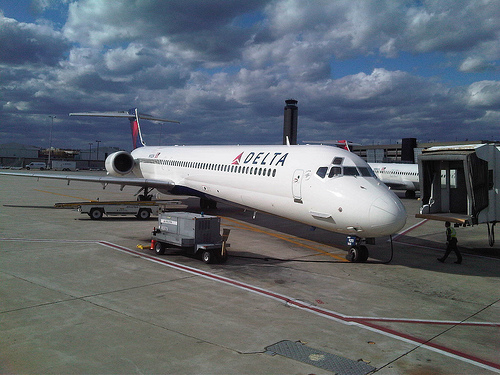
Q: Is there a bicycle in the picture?
A: No, there are no bicycles.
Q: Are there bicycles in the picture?
A: No, there are no bicycles.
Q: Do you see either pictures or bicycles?
A: No, there are no bicycles or pictures.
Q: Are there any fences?
A: No, there are no fences.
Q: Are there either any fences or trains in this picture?
A: No, there are no fences or trains.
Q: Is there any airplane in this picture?
A: Yes, there is an airplane.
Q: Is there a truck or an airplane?
A: Yes, there is an airplane.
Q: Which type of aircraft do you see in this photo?
A: The aircraft is an airplane.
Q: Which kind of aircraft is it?
A: The aircraft is an airplane.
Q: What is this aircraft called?
A: That is an airplane.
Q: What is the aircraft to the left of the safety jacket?
A: The aircraft is an airplane.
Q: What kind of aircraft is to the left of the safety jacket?
A: The aircraft is an airplane.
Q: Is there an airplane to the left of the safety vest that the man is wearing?
A: Yes, there is an airplane to the left of the safety jacket.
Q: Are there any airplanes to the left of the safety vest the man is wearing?
A: Yes, there is an airplane to the left of the safety jacket.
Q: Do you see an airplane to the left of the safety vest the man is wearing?
A: Yes, there is an airplane to the left of the safety jacket.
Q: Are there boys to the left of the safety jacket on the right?
A: No, there is an airplane to the left of the safety jacket.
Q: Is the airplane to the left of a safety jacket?
A: Yes, the airplane is to the left of a safety jacket.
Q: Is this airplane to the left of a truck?
A: No, the airplane is to the left of a safety jacket.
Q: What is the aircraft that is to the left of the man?
A: The aircraft is an airplane.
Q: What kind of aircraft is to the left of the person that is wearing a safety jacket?
A: The aircraft is an airplane.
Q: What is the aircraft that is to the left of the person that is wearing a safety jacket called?
A: The aircraft is an airplane.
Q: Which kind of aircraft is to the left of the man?
A: The aircraft is an airplane.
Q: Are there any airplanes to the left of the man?
A: Yes, there is an airplane to the left of the man.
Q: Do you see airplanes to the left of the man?
A: Yes, there is an airplane to the left of the man.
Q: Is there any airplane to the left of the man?
A: Yes, there is an airplane to the left of the man.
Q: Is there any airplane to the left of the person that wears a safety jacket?
A: Yes, there is an airplane to the left of the man.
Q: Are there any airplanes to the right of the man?
A: No, the airplane is to the left of the man.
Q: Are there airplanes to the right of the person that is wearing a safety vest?
A: No, the airplane is to the left of the man.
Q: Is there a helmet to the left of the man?
A: No, there is an airplane to the left of the man.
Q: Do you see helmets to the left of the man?
A: No, there is an airplane to the left of the man.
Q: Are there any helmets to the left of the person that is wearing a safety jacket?
A: No, there is an airplane to the left of the man.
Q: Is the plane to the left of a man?
A: Yes, the plane is to the left of a man.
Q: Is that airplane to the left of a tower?
A: No, the airplane is to the left of a man.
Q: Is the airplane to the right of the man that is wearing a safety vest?
A: No, the airplane is to the left of the man.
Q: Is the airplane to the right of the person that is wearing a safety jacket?
A: No, the airplane is to the left of the man.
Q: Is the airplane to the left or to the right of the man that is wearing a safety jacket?
A: The airplane is to the left of the man.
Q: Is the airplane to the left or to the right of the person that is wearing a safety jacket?
A: The airplane is to the left of the man.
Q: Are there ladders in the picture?
A: No, there are no ladders.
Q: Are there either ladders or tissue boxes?
A: No, there are no ladders or tissue boxes.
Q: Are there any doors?
A: Yes, there is a door.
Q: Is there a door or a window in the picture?
A: Yes, there is a door.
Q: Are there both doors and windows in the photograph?
A: Yes, there are both a door and a window.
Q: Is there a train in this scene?
A: No, there are no trains.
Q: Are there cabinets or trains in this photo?
A: No, there are no trains or cabinets.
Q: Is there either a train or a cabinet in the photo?
A: No, there are no trains or cabinets.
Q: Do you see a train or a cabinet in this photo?
A: No, there are no trains or cabinets.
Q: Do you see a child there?
A: No, there are no children.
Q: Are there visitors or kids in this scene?
A: No, there are no kids or visitors.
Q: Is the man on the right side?
A: Yes, the man is on the right of the image.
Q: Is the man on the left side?
A: No, the man is on the right of the image.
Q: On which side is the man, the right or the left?
A: The man is on the right of the image.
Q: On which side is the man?
A: The man is on the right of the image.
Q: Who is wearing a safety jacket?
A: The man is wearing a safety jacket.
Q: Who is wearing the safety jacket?
A: The man is wearing a safety jacket.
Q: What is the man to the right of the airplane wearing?
A: The man is wearing a safety jacket.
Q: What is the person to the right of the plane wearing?
A: The man is wearing a safety jacket.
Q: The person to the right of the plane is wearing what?
A: The man is wearing a safety jacket.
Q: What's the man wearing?
A: The man is wearing a safety jacket.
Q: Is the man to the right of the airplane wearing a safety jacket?
A: Yes, the man is wearing a safety jacket.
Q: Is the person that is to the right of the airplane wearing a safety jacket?
A: Yes, the man is wearing a safety jacket.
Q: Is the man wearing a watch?
A: No, the man is wearing a safety jacket.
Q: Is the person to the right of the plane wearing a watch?
A: No, the man is wearing a safety jacket.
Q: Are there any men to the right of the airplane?
A: Yes, there is a man to the right of the airplane.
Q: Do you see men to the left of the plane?
A: No, the man is to the right of the plane.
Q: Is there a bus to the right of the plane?
A: No, there is a man to the right of the plane.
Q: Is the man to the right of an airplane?
A: Yes, the man is to the right of an airplane.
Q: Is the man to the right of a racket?
A: No, the man is to the right of an airplane.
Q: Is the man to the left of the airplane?
A: No, the man is to the right of the airplane.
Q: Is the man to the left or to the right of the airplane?
A: The man is to the right of the airplane.